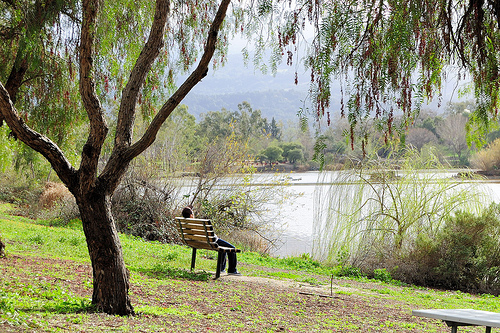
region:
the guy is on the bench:
[166, 206, 274, 294]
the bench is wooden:
[165, 208, 263, 280]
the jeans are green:
[218, 236, 255, 265]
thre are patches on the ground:
[182, 276, 333, 322]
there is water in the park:
[233, 153, 486, 228]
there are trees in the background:
[233, 97, 436, 127]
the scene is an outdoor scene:
[3, 2, 450, 328]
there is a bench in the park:
[418, 301, 497, 331]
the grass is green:
[132, 235, 180, 261]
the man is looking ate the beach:
[177, 203, 264, 280]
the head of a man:
[181, 205, 194, 220]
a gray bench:
[406, 302, 498, 328]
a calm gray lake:
[116, 167, 498, 279]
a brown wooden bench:
[172, 213, 242, 255]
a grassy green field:
[0, 200, 499, 331]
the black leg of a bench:
[188, 242, 200, 269]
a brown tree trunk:
[0, 0, 232, 316]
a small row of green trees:
[251, 137, 306, 169]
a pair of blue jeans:
[213, 237, 240, 274]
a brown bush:
[38, 180, 70, 207]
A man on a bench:
[156, 197, 269, 285]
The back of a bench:
[175, 215, 215, 242]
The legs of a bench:
[181, 246, 226, 272]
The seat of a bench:
[215, 240, 237, 250]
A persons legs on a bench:
[215, 225, 242, 276]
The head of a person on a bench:
[178, 200, 198, 221]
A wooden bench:
[170, 212, 234, 279]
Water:
[271, 175, 364, 248]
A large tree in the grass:
[34, 10, 182, 320]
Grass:
[29, 225, 67, 251]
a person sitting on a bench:
[166, 181, 248, 282]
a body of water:
[157, 143, 492, 263]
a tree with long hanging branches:
[28, 5, 481, 195]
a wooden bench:
[168, 210, 228, 277]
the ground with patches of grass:
[78, 295, 359, 331]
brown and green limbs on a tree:
[307, 30, 459, 147]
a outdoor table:
[440, 304, 489, 331]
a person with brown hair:
[161, 189, 220, 257]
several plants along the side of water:
[126, 155, 486, 260]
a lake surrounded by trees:
[141, 145, 481, 240]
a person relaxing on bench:
[171, 198, 264, 291]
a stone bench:
[416, 307, 498, 329]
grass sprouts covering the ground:
[167, 289, 237, 326]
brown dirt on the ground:
[241, 299, 261, 314]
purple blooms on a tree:
[305, 94, 339, 125]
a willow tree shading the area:
[16, 86, 153, 319]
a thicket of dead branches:
[122, 191, 165, 234]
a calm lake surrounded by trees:
[301, 184, 311, 227]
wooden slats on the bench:
[183, 220, 218, 240]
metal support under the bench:
[444, 321, 461, 328]